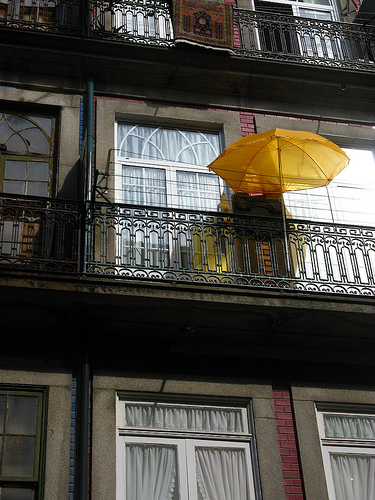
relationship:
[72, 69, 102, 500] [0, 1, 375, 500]
pipe on building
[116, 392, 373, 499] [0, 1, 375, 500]
windows on building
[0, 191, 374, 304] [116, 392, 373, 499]
railing near windows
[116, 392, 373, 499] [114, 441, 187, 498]
windows above window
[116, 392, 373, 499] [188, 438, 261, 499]
windows above window